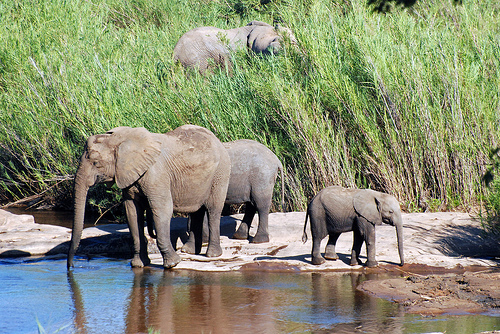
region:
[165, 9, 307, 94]
elephant located in grass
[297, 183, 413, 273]
baby elephant located near water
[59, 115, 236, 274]
adult elephant with trunk hanging down to water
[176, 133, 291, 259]
younger elephant standing behind larger elephant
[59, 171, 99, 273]
an elephants trunk hanging down to water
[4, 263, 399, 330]
small pool of water along rock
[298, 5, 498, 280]
tall grass growing along water with baby elephant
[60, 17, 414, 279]
family of four elephants along the water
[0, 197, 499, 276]
rock river bank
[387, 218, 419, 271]
baby elephant gray colored trunk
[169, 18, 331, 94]
elephant in the tall grass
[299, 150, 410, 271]
baby elephant at the watering hole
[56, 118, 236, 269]
large elephant drinking from the watering hole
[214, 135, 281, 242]
back of an elephant standing behind the larger one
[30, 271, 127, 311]
water in the watering hole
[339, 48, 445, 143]
tall grass behind the watering hole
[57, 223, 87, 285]
wet trunk from drinking water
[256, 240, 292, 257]
wet rocks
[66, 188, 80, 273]
elephant truck reaching for water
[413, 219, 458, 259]
ground by the watering hole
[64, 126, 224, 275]
an elephant drinking from the stream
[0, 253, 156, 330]
the stream is blue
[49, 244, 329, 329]
the elephant reflection in the stream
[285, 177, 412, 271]
a baby elephant drinking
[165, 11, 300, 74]
an elephant in the grass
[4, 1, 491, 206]
the grass is very tall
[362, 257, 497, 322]
rocks in the stream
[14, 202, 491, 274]
dry rocks by the stream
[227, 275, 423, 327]
ripples in the stream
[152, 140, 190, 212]
wrinkles on the elephant's back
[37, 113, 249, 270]
the elephants beside the water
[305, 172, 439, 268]
the young elephant beside the water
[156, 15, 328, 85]
the elephant in the grass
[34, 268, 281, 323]
the water is calm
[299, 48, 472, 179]
the tall grass is green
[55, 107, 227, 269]
the elephant is drinking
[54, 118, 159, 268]
the head of the elephant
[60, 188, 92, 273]
the trunk of the elephant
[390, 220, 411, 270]
the trunk of the elephant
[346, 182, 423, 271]
the head of the elephant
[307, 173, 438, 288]
small elephant by water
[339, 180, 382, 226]
right ear on small elephant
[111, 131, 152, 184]
right ear on large elephant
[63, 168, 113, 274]
trunk on large elephant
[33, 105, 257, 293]
large elephant in water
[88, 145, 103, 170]
left eye on elephant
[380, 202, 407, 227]
right eye on elephant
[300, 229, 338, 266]
right leg on elephant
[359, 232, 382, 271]
right leg on elephant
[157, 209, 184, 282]
left leg on elephant